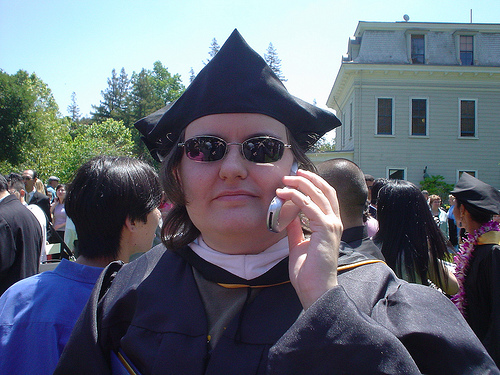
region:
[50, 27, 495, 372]
graduate talking on the phone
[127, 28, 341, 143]
black graduation hat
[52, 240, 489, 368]
black graduation gown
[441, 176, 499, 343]
graduate standing in the background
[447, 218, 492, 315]
lei around the graduate's neck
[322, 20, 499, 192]
white building in the background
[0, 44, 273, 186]
pine trees in the background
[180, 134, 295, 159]
sunglasses on the person's face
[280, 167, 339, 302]
left hand of the graduate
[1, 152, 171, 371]
man in blue standing behind the graduate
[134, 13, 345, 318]
a man on a phone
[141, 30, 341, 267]
a woman on the phone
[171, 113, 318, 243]
a man wearing sunglasses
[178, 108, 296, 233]
a woman wearing sunglasses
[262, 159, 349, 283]
a hand holding a cell phone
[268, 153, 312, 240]
a shiny silver cell phone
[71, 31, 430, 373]
a man wearing a cap and gown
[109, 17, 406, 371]
a woman wearing a cap and gown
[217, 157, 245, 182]
the nose on a man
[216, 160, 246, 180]
the nose on a woman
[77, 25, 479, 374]
woman in scholarly event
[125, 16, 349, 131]
hat on top woman's head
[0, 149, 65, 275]
group of people attending event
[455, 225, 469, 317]
decorative lau around person's neck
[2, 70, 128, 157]
group of trees in background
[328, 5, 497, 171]
building on lawn outside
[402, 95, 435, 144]
verticle window on building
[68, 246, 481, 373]
gown worn by woman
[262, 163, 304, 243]
phone in woman's hand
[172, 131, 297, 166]
sunglasses worn by woman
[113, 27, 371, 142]
This lady is wearing a hat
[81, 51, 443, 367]
This person just graduated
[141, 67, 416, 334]
This person is on the phone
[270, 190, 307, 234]
This is a cell phone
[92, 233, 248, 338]
The person's robe is black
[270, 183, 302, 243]
This cell phone is silver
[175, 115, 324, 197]
The person has on sunglasses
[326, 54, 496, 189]
This house is light green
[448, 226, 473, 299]
This person has on a necklack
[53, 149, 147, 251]
this person has black hair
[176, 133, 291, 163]
the sunglasses on the woman's face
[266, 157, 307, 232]
the cellphone the woman is holding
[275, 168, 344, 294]
the woman's left hand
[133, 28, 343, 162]
the black cap on the woman's head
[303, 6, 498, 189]
the large building in the back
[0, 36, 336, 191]
the green trees behind the people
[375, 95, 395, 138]
the window on the building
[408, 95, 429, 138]
the window on the building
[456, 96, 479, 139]
the window on the building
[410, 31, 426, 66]
the window on the building